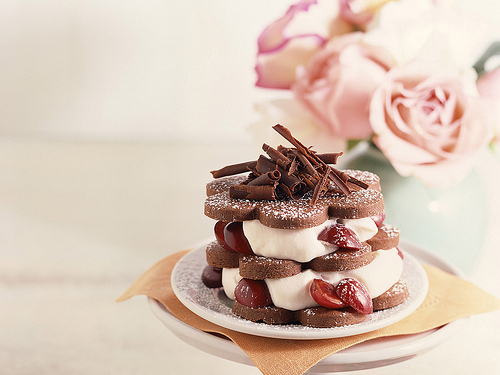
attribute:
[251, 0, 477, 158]
roses — light pink, dark pink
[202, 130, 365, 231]
chocolate — shredded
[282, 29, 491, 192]
roses — pink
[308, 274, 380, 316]
cherry — piece 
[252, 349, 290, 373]
napkin — tan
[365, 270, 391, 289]
cream — whipped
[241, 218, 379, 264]
whipped cream — white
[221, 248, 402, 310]
whipped cream — white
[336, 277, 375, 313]
cherry — red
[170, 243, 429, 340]
plate — small, round, white, tiny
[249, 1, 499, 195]
roses — light pink, pink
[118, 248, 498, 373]
napkin — orange, brown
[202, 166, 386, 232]
cake — flower shaped, chocolate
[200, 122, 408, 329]
dessert — chocolate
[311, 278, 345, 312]
cherry — red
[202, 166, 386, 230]
pastry — chocolate, flower shaped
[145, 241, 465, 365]
plate — round, white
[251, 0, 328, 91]
edge — darker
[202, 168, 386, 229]
cookie — brown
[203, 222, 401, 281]
cookie — brown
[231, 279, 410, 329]
cookie — brown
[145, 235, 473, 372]
plate — small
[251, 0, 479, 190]
flower bunch — pink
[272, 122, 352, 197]
shaving — chocolate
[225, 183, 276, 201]
shaving — chocolate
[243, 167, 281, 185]
shaving — chocolate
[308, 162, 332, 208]
shaving — chocolate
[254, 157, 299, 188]
shaving — chocolate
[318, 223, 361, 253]
cherry —  a piece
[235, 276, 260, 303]
cherry —  a piece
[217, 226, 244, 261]
cherry —  a piece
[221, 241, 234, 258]
cherry —  a piece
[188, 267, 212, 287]
cherry —  a piece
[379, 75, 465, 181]
rose — pink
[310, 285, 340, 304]
cherry — half, red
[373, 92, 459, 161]
rose — pink